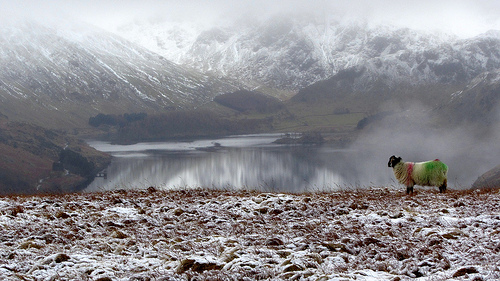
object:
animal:
[386, 154, 451, 196]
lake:
[82, 131, 391, 198]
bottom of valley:
[34, 93, 485, 204]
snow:
[0, 189, 499, 280]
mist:
[1, 4, 496, 63]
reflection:
[113, 152, 328, 189]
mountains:
[4, 3, 214, 103]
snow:
[4, 3, 496, 99]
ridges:
[0, 34, 296, 90]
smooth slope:
[118, 43, 218, 100]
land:
[68, 100, 393, 196]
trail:
[78, 119, 129, 155]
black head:
[387, 155, 403, 168]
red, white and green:
[402, 159, 446, 184]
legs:
[408, 185, 416, 195]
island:
[196, 137, 234, 154]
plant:
[215, 86, 289, 116]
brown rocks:
[35, 203, 442, 268]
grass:
[4, 185, 487, 203]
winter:
[2, 4, 498, 280]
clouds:
[3, 2, 495, 38]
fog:
[46, 84, 477, 187]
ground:
[1, 187, 499, 279]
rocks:
[451, 263, 489, 279]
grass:
[1, 200, 499, 269]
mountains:
[137, 11, 334, 81]